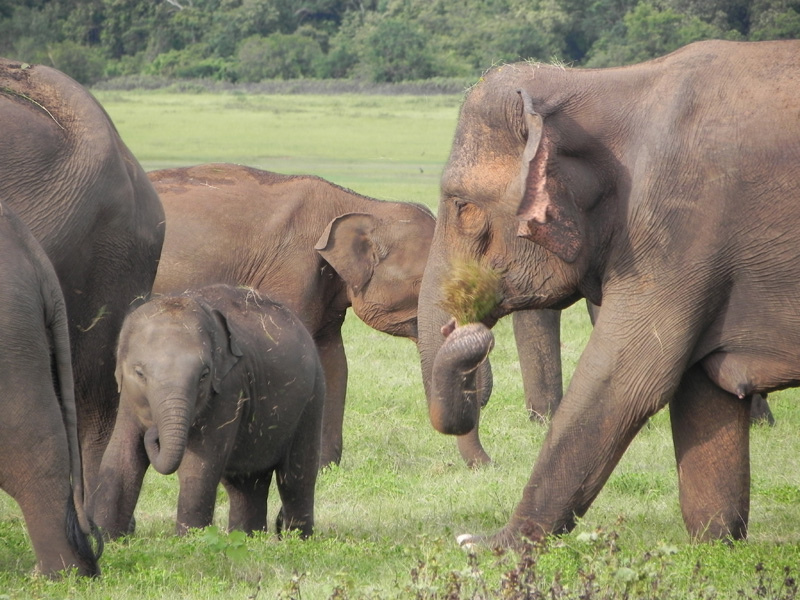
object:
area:
[0, 0, 800, 84]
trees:
[118, 3, 426, 82]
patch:
[212, 563, 235, 592]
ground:
[0, 515, 491, 600]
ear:
[314, 212, 389, 297]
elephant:
[143, 163, 499, 474]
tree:
[219, 0, 277, 56]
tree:
[369, 18, 426, 80]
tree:
[450, 9, 567, 75]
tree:
[144, 43, 226, 78]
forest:
[0, 0, 800, 83]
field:
[0, 90, 800, 600]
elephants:
[0, 38, 800, 585]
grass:
[436, 261, 504, 327]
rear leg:
[0, 359, 97, 580]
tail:
[25, 234, 104, 563]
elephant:
[86, 276, 324, 537]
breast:
[705, 351, 775, 399]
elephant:
[417, 40, 800, 568]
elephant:
[0, 59, 165, 581]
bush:
[357, 18, 432, 80]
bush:
[466, 30, 547, 70]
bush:
[590, 4, 697, 71]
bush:
[142, 48, 183, 76]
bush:
[172, 63, 216, 78]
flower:
[455, 533, 476, 566]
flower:
[576, 530, 597, 544]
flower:
[650, 541, 680, 560]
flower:
[626, 570, 640, 591]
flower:
[693, 565, 699, 577]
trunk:
[417, 248, 495, 435]